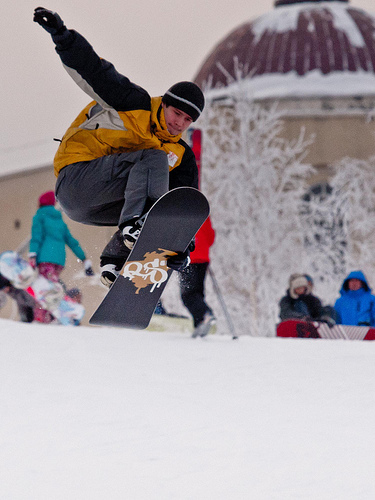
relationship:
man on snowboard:
[34, 4, 226, 312] [91, 184, 215, 326]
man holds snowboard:
[34, 4, 226, 312] [91, 184, 215, 326]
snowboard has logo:
[91, 184, 215, 326] [123, 245, 174, 293]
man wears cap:
[34, 4, 226, 312] [163, 74, 213, 122]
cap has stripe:
[163, 74, 213, 122] [165, 90, 199, 104]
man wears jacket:
[34, 4, 226, 312] [54, 102, 168, 167]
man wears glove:
[34, 4, 226, 312] [33, 8, 75, 42]